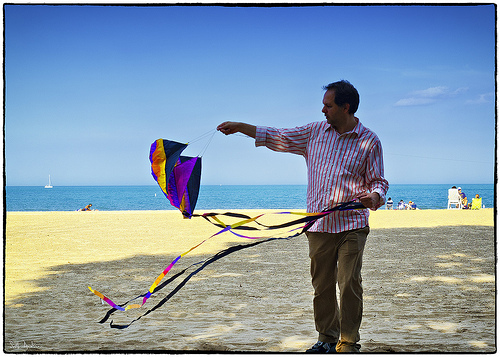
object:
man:
[215, 78, 387, 353]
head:
[320, 80, 361, 126]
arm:
[245, 121, 313, 157]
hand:
[215, 120, 242, 136]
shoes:
[303, 332, 362, 352]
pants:
[301, 226, 372, 342]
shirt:
[255, 119, 389, 234]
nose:
[321, 106, 331, 113]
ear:
[346, 101, 353, 113]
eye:
[326, 101, 334, 108]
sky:
[3, 5, 495, 187]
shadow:
[6, 223, 496, 357]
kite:
[148, 139, 206, 220]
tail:
[192, 193, 363, 239]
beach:
[6, 208, 495, 351]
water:
[7, 183, 495, 211]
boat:
[43, 166, 55, 190]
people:
[385, 186, 486, 211]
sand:
[214, 248, 308, 305]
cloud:
[397, 84, 479, 110]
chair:
[446, 188, 461, 208]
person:
[450, 184, 469, 207]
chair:
[471, 198, 485, 209]